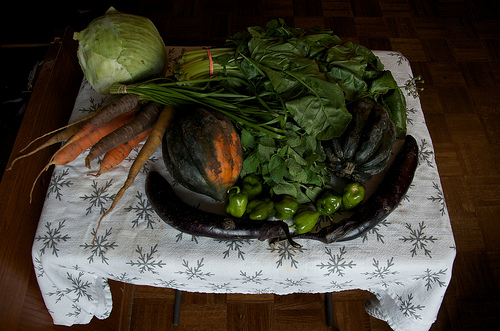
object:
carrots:
[27, 92, 141, 205]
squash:
[160, 105, 244, 204]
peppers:
[287, 204, 322, 235]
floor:
[450, 9, 498, 278]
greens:
[240, 17, 408, 140]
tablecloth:
[30, 45, 458, 330]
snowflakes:
[396, 220, 439, 260]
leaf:
[270, 70, 359, 142]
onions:
[104, 76, 291, 140]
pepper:
[224, 185, 249, 219]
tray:
[32, 45, 456, 257]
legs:
[169, 289, 182, 328]